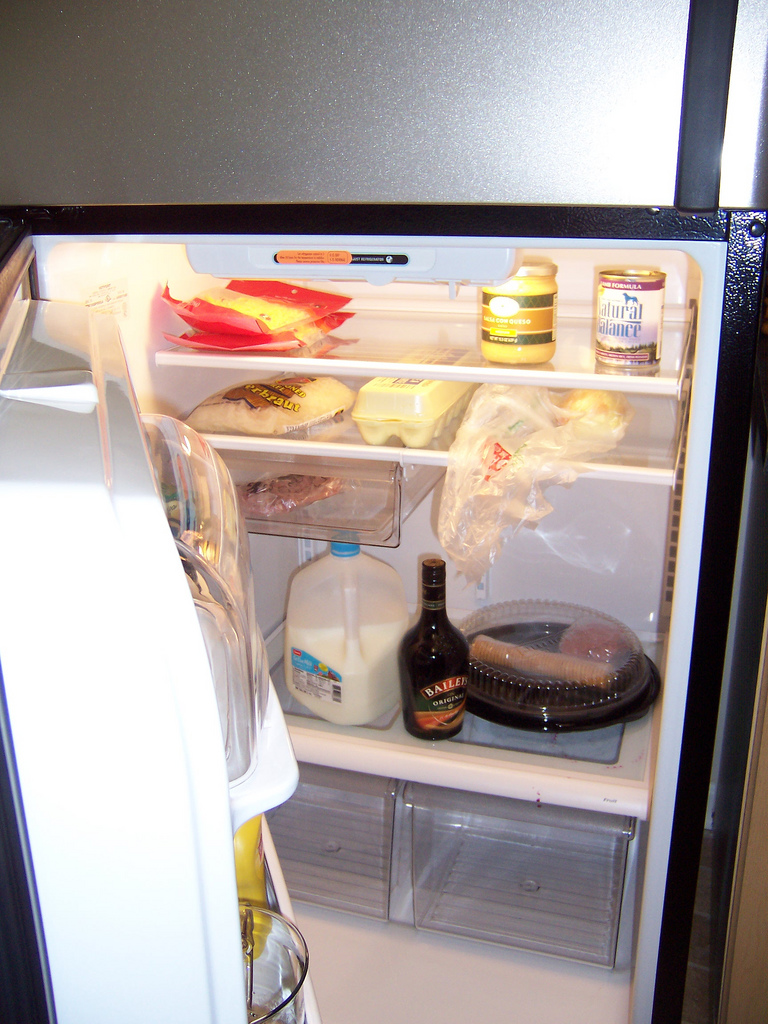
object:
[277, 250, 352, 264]
orange sticker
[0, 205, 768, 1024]
white fridge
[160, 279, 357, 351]
bags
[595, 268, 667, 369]
can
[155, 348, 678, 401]
top shelf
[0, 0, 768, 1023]
door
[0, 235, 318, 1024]
refrigerator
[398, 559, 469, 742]
black bottle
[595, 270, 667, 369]
purple/white can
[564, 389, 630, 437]
yellow onion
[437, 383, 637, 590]
clear bag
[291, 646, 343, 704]
blue/white label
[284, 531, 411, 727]
plastic jug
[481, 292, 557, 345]
green/orange label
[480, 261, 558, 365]
glass jar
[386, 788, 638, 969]
bin